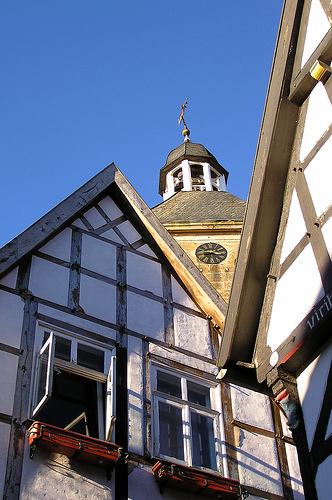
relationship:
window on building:
[28, 327, 139, 454] [32, 185, 236, 485]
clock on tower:
[195, 241, 228, 265] [152, 106, 243, 262]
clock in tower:
[195, 241, 228, 265] [152, 106, 243, 262]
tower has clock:
[152, 106, 243, 262] [195, 241, 228, 265]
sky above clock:
[46, 32, 147, 99] [195, 241, 228, 265]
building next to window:
[32, 185, 236, 485] [28, 327, 139, 454]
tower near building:
[152, 106, 243, 262] [32, 185, 236, 485]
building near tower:
[32, 185, 236, 485] [152, 106, 243, 262]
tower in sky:
[152, 106, 243, 262] [46, 32, 147, 99]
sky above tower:
[46, 32, 147, 99] [152, 106, 243, 262]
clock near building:
[195, 241, 228, 265] [32, 185, 236, 485]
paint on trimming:
[280, 341, 310, 360] [276, 336, 320, 366]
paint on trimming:
[224, 286, 241, 363] [214, 260, 248, 366]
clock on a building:
[192, 238, 231, 266] [142, 91, 253, 311]